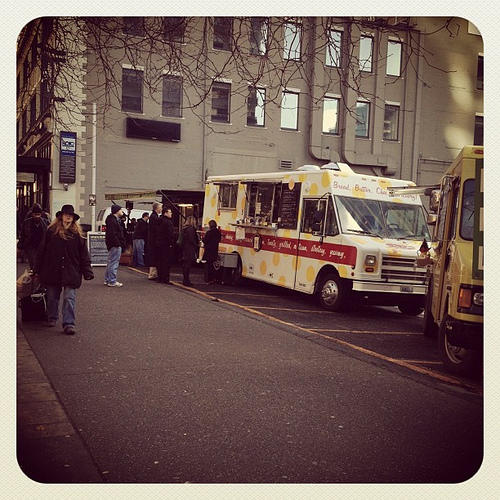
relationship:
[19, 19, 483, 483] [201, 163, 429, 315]
scene shows truck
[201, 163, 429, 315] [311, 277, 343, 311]
truck has front wheel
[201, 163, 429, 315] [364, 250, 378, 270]
truck has a front headlight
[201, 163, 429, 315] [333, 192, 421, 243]
truck has front windshield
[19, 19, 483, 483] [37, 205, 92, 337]
scene shows walking person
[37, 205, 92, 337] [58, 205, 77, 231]
walking person has head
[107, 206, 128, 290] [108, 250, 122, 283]
man has pants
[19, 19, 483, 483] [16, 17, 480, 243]
scene shows building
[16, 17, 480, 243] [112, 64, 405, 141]
building has windows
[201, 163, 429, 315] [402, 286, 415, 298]
truck has license plate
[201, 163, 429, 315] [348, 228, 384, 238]
truck has windshield wiper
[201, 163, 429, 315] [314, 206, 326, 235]
truck has side view mirror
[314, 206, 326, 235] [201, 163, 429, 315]
side view mirror shows rear behind truck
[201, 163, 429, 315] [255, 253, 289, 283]
truck has polka dots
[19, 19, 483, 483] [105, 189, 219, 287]
scene shows crowd of people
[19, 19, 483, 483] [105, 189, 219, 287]
scene shows line of people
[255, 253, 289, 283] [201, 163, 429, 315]
polka dots are yellow and on truck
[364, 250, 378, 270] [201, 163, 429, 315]
front headlight part of truck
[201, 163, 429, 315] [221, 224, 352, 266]
truck has stripe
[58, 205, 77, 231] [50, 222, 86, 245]
head of woman has long blonde hair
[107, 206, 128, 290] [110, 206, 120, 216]
man has beanie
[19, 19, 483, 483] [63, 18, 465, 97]
scene shows tree branches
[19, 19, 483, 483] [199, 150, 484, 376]
scene shows 2 parked food trucks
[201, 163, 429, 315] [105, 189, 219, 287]
food truck has a crowd of people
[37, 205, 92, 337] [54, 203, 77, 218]
walking person has black hat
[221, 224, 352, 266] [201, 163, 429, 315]
stripe runs alolngside of food truck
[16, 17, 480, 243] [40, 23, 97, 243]
building has a corner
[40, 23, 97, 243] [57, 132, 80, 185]
corner has sign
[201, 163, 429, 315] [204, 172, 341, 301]
truck for food has side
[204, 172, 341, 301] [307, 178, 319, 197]
side of truck features dot